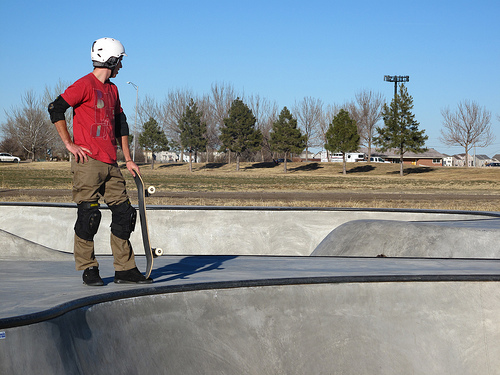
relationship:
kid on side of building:
[47, 35, 158, 283] [175, 32, 225, 78]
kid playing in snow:
[47, 35, 158, 283] [175, 32, 225, 78]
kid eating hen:
[47, 35, 158, 283] [175, 32, 225, 78]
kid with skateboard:
[47, 35, 161, 283] [130, 168, 162, 279]